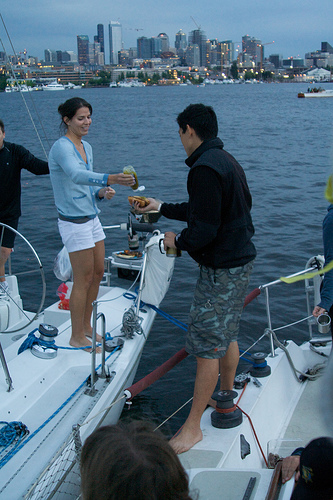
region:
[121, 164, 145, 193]
Relish being squirted out of bottle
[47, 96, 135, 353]
Young woman standing on boat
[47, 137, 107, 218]
Women's long sleeve blue top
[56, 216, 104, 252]
Women's white shorts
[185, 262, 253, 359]
Men's camouflage cargo shorts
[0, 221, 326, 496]
Two boats tied together on the ocean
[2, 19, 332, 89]
City skyline next to the ocean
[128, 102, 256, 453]
Man standing on a boat holding a hot dog.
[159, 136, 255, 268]
Men's black fleece jacket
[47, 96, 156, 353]
Woman putting relish on a hot dog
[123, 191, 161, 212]
A hand holding a hot dog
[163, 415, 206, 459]
A bare foot standing on a boat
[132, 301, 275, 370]
A blue rope between two boats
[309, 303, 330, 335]
A hand holding a silver mug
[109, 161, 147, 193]
A hand holding a bottle of relish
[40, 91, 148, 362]
A woman standing on a boat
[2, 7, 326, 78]
A city scape in the background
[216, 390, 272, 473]
A red rope on one boat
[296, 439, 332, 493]
A black hat on a person's head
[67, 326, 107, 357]
A woman's bare feet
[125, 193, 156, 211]
HOT DOG AND BUN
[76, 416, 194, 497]
BACK OF SOMEONES HEAD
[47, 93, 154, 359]
WOMAN PUTTING RELISH ON A HOT DOG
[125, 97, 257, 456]
MAN HOLDING A HOT DOG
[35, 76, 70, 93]
WHITE BOAT IN THE DISTANCE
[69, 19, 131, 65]
TALL BUILDINGS IN THE BACKGROUND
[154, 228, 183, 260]
CUP ON A MAN'S HAND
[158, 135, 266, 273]
BLACK JACKET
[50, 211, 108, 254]
WHITE SHORTS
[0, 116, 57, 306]
MAN ON THE LEFT WEARING BLACK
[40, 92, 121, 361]
a woman standing on a boat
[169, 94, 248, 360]
a man standing on a boat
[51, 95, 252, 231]
a woman putting relish on a man's hot dog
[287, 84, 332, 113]
people on a boat in the water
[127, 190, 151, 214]
a hot dog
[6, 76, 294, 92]
boats on a river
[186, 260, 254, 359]
camouflage shorts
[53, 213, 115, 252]
white shorts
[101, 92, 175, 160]
the water on a river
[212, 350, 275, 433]
boat ties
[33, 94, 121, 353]
Woman standing on white boat.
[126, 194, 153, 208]
Man holding a hot dog.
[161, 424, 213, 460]
A man's bear foot.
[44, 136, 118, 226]
Woman wearing blue shirt.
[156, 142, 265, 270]
Man wearing black jacket.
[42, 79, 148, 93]
Boats docked at marina.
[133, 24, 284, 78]
City lights in distance.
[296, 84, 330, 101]
Boat with more people.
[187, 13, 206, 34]
Crane on top of building.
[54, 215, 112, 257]
Woman wearing white shorts.